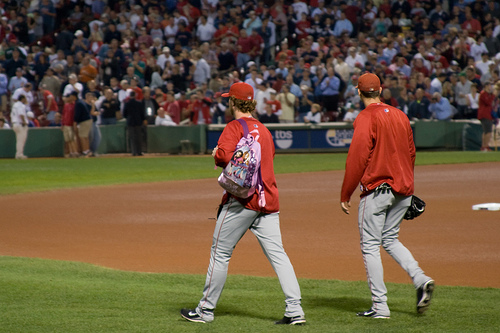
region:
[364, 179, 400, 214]
Gloves in back pocket of man's pants.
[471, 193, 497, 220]
White baseball base.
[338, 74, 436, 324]
Man wearing gray and red baseball uniform.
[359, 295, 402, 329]
Man wearing nike shoes.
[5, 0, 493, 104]
Baseball fans watching game.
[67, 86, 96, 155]
Man in tan shorts talking.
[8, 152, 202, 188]
Green turf along infield.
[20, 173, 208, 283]
Red dirt on infield.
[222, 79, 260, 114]
Man's curly brown hair.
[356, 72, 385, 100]
Fitted baseball cap on man's head.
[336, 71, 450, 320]
Man wearing red jacket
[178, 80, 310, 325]
Man wearing gray pants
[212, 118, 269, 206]
Pink backpack on man's back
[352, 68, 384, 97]
Red hat on man's head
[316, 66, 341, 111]
Man standing in blue shirt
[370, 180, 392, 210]
Gloves in man's back pocket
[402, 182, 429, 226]
Mitt in man's right hand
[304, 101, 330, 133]
Boy wearing white shirt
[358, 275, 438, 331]
Nike shoes on man's feet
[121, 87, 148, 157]
Man wearing a black jacket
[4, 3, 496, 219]
spectators at a baseball game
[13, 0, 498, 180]
the spectators are giving a standing ovation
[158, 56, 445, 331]
baseball players are walking on the field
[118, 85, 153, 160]
an umpire is standing towards the stands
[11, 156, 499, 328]
the baseball field is red clay and grass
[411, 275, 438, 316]
the baseball player is wearing cleats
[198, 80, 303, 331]
the player is carrying a backpack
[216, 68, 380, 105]
the players are wearing red baseball caps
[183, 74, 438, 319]
the players are wearing baseball uniforms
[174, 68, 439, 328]
the players uniforms are red and white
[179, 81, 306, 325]
Baseball player carrying pink backpack.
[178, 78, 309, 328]
Baseball player walking with pink and purple backpack.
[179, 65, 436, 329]
Two baseball players walking on a field.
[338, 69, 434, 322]
Baseball player walking and looking at crowd.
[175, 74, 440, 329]
Two baseball players walking on field grass.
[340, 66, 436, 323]
Baseball player walking across grass with glove in hand.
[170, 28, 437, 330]
Baseball players walking in packed stadium.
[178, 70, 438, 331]
Two baseball players walking side by side.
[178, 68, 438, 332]
Two baseball players in red walking.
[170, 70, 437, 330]
Two baseball players in red walking in grass.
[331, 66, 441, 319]
a man wearing orange and white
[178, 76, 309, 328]
a man wearing orange and white carrying a bag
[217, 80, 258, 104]
an orange baseball cap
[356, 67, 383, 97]
an orange baseball cap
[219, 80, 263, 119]
the head of a man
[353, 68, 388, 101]
the head of a man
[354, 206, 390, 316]
the leg of a man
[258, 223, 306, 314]
the leg of a man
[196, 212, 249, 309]
the leg of a man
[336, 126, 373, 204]
the arm of a man